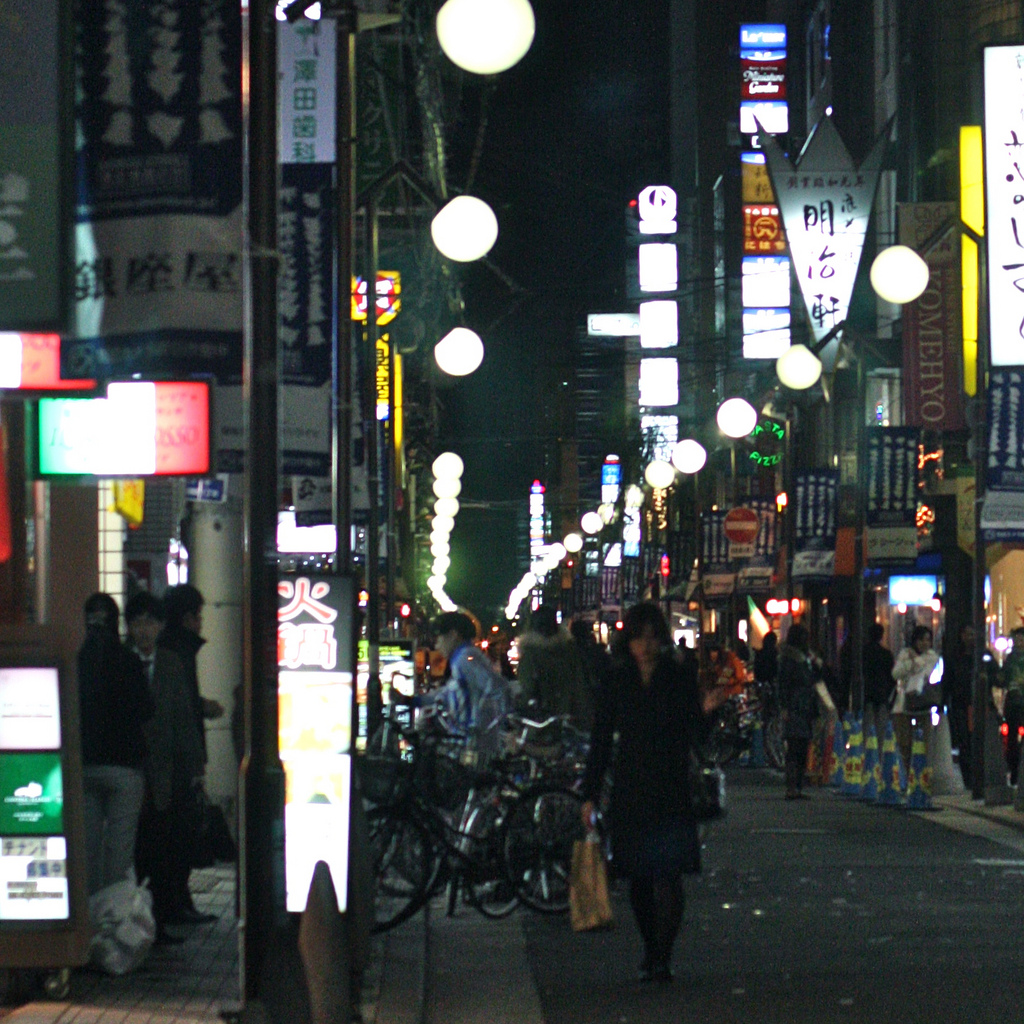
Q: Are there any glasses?
A: No, there are no glasses.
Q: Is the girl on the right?
A: Yes, the girl is on the right of the image.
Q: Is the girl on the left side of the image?
A: No, the girl is on the right of the image.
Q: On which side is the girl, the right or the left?
A: The girl is on the right of the image.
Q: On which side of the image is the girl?
A: The girl is on the right of the image.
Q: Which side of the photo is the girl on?
A: The girl is on the right of the image.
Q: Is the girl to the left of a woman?
A: No, the girl is to the right of a woman.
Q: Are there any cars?
A: No, there are no cars.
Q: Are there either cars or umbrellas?
A: No, there are no cars or umbrellas.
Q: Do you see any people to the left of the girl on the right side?
A: Yes, there are people to the left of the girl.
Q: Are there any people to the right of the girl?
A: No, the people are to the left of the girl.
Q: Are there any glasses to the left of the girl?
A: No, there are people to the left of the girl.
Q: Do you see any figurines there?
A: No, there are no figurines.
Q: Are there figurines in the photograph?
A: No, there are no figurines.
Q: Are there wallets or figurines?
A: No, there are no figurines or wallets.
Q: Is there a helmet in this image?
A: No, there are no helmets.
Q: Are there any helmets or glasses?
A: No, there are no helmets or glasses.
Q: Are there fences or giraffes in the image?
A: No, there are no fences or giraffes.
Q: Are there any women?
A: Yes, there is a woman.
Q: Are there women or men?
A: Yes, there is a woman.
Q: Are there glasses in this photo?
A: No, there are no glasses.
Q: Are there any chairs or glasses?
A: No, there are no glasses or chairs.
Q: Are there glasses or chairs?
A: No, there are no glasses or chairs.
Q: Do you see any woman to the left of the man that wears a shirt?
A: No, the woman is to the right of the man.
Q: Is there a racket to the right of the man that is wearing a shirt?
A: No, there is a woman to the right of the man.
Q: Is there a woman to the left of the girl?
A: Yes, there is a woman to the left of the girl.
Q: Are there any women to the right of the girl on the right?
A: No, the woman is to the left of the girl.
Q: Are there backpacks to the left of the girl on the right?
A: No, there is a woman to the left of the girl.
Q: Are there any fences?
A: No, there are no fences.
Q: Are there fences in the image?
A: No, there are no fences.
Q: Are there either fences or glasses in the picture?
A: No, there are no fences or glasses.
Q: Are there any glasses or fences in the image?
A: No, there are no fences or glasses.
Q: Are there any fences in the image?
A: No, there are no fences.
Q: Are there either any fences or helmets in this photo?
A: No, there are no fences or helmets.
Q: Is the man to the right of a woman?
A: No, the man is to the left of a woman.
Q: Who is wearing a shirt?
A: The man is wearing a shirt.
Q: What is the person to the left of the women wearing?
A: The man is wearing a shirt.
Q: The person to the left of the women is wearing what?
A: The man is wearing a shirt.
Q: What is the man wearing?
A: The man is wearing a shirt.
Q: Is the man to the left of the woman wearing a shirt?
A: Yes, the man is wearing a shirt.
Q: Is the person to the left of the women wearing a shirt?
A: Yes, the man is wearing a shirt.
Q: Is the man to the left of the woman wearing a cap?
A: No, the man is wearing a shirt.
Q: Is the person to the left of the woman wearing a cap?
A: No, the man is wearing a shirt.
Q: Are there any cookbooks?
A: No, there are no cookbooks.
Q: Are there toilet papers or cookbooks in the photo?
A: No, there are no cookbooks or toilet papers.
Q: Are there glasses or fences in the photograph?
A: No, there are no fences or glasses.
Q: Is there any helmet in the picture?
A: No, there are no helmets.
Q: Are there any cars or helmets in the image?
A: No, there are no helmets or cars.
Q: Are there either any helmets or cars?
A: No, there are no helmets or cars.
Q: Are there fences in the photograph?
A: No, there are no fences.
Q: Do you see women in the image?
A: Yes, there are women.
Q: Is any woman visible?
A: Yes, there are women.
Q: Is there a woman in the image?
A: Yes, there are women.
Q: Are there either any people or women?
A: Yes, there are women.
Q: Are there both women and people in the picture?
A: Yes, there are both women and people.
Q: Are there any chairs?
A: No, there are no chairs.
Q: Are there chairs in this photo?
A: No, there are no chairs.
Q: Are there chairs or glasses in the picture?
A: No, there are no chairs or glasses.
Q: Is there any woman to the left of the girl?
A: Yes, there are women to the left of the girl.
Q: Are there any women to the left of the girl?
A: Yes, there are women to the left of the girl.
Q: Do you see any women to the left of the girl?
A: Yes, there are women to the left of the girl.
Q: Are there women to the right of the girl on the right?
A: No, the women are to the left of the girl.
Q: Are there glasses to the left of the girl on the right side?
A: No, there are women to the left of the girl.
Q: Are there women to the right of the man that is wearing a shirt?
A: Yes, there are women to the right of the man.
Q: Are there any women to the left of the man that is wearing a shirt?
A: No, the women are to the right of the man.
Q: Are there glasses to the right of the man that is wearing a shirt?
A: No, there are women to the right of the man.